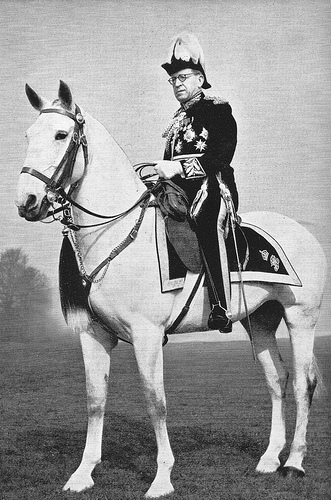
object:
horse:
[13, 79, 328, 498]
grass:
[0, 337, 331, 498]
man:
[151, 27, 240, 335]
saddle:
[155, 174, 231, 273]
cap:
[160, 30, 213, 89]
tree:
[0, 247, 48, 339]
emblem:
[259, 250, 270, 262]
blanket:
[153, 198, 303, 293]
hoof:
[62, 467, 98, 497]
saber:
[223, 186, 257, 364]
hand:
[153, 160, 182, 180]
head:
[170, 58, 205, 102]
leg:
[130, 327, 176, 499]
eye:
[55, 129, 70, 142]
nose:
[15, 193, 38, 213]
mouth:
[33, 202, 49, 222]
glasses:
[168, 71, 197, 85]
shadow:
[15, 403, 282, 488]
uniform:
[162, 93, 239, 312]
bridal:
[21, 108, 89, 212]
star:
[194, 139, 207, 152]